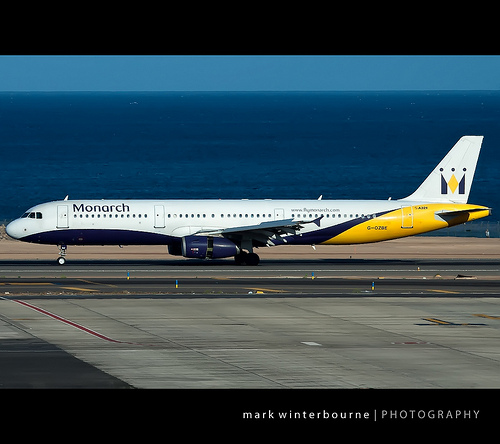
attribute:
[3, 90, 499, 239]
water — ocean, large body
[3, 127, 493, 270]
jet — yellow, white, large, commercial, monarch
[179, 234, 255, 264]
left engine — blue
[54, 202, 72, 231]
door — metal, front exit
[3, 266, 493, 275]
line — white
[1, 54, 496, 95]
sky — clear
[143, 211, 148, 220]
window — small, passenger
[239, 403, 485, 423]
text — white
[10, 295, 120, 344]
stripe — colorful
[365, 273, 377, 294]
post — short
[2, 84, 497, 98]
horizon — clear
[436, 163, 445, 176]
dot — blue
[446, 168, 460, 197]
diamond — yellow